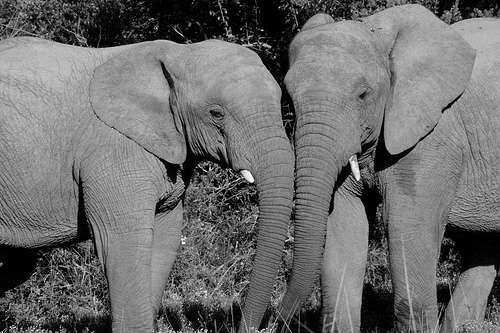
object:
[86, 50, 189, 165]
ear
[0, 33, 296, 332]
elephant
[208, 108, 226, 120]
eye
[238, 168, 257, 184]
tusk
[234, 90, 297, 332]
trunk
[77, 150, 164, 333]
leg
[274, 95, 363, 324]
nose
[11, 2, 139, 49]
trees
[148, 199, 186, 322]
legs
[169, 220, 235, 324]
bushes